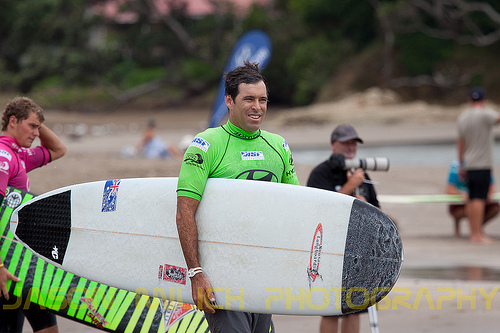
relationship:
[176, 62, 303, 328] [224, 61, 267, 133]
man has head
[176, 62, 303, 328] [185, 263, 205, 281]
man has wrist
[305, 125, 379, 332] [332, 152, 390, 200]
guy has camera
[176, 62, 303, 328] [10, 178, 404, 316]
man has surfboard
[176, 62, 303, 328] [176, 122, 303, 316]
man has shirt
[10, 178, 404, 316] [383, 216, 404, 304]
surfboard has end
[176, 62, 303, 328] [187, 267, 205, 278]
man has bracelet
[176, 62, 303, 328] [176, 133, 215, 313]
man has arm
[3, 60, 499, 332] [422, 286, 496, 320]
people on beach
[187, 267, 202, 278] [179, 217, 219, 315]
watch on arm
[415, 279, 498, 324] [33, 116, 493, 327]
sand on beach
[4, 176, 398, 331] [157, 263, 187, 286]
surfboard has logo